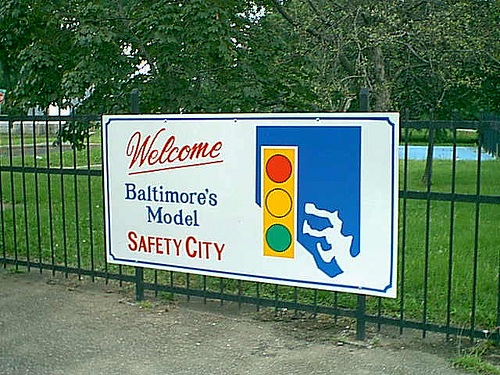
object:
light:
[260, 148, 298, 258]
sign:
[100, 111, 399, 298]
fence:
[19, 88, 470, 345]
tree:
[136, 20, 364, 103]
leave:
[142, 57, 215, 94]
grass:
[92, 202, 99, 227]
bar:
[53, 99, 109, 286]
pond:
[408, 141, 486, 161]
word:
[120, 127, 224, 180]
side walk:
[73, 320, 235, 373]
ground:
[35, 297, 106, 342]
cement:
[28, 291, 96, 317]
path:
[80, 310, 118, 342]